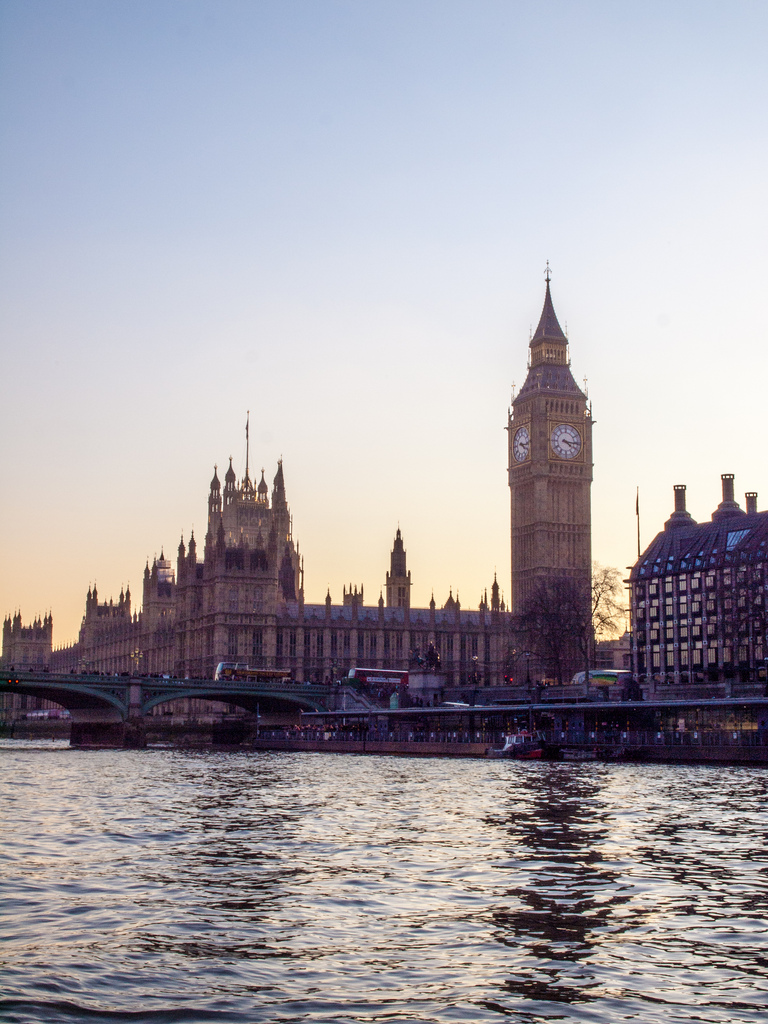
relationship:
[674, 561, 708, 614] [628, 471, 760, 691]
window on building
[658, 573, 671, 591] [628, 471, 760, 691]
window on building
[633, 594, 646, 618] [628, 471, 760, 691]
window on building